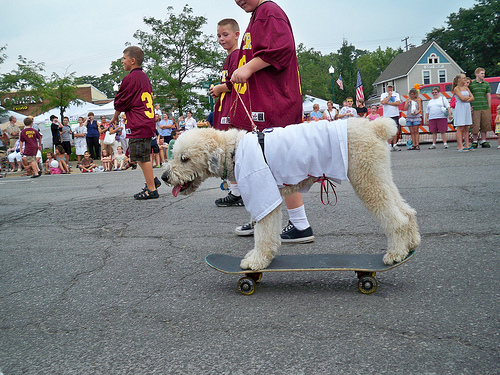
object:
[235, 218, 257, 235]
sneaker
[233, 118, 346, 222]
t-shirt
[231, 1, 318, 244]
boy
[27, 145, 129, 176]
child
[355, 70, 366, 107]
american flag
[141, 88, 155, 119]
3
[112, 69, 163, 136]
shirt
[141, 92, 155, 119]
number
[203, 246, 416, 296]
skateboard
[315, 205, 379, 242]
ground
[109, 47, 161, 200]
kid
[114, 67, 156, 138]
jersey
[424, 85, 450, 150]
lady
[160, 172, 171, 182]
nose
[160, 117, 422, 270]
dog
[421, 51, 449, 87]
windows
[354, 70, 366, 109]
flag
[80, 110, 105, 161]
person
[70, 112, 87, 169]
person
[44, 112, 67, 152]
person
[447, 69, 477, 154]
person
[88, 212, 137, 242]
crack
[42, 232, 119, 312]
crack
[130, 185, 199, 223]
crack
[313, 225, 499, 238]
crack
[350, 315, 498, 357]
crack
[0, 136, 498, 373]
road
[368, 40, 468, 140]
blue house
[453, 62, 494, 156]
couple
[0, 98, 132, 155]
tents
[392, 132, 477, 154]
curb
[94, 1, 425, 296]
parade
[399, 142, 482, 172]
roadside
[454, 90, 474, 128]
sundress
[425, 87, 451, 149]
woman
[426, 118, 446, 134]
shorts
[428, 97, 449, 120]
top